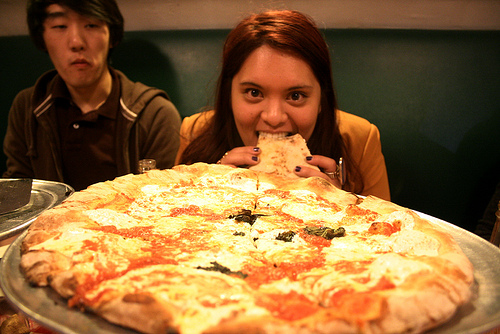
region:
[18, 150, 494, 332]
A large pizza on a silver tray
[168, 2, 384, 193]
a girl eating a piece of pizza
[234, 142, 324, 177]
the girl has blue nail polish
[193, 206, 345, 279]
basil is on the pizza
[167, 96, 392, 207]
girl is wearing a yellow shirt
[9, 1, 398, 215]
boy watching the girl eat pizza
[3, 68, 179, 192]
boy is wearing a brown hoodie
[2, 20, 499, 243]
the back of a green booth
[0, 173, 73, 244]
an empty silver tray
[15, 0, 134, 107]
a boy of Asian descent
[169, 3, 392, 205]
girl making silly face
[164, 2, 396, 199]
girl eating pizza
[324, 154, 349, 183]
large ring on girl's left hand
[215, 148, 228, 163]
rings on girl's right hand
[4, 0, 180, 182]
boy in faded hoodie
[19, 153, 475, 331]
large oven-fired pizza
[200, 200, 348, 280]
basil pesto on pizza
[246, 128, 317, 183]
pizza in girl's hands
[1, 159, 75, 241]
empty pizza tray on left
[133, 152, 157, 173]
coat of arms on boy's hoodie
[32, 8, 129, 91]
The man is impressed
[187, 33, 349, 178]
She is eating pizza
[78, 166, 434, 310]
The pizza is shiny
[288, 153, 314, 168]
her Fingernails are black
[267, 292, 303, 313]
The tomatoes are red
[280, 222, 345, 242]
The olives are black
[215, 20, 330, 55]
Her hair is red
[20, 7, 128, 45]
His hair is black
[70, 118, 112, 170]
His shirt is brown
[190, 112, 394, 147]
Her coat is orange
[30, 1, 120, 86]
man with tongue in cheek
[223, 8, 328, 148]
woman eating slice of pizza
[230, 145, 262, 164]
two fingers with dark nail polish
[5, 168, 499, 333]
pizza on a silver tray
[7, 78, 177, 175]
brown shirt and brown hoodie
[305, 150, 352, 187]
finger with large ring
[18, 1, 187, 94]
head of man with shadow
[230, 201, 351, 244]
dark garnish on top of pizza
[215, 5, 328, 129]
woman's face with reddish hair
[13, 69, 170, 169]
brown hoodie with white stripes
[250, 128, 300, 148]
THE GIRL IS BITING THE PIZZA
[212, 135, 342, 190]
THE GIRL IS HOLDING A PIZZA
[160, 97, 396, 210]
THE GIRL IS WEARING A YELLOW JACKET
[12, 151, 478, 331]
THE PIZZA IS ON A TRAY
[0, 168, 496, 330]
THE PIZZA IS VERY BIG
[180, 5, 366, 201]
THE GIRL IS EATING THE PIZZA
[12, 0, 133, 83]
THE BOY HAS BLACK HAIR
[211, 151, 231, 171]
THE GIRL IS WEARING RINGS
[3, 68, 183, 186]
THE BOY IS WEARING A HOODIE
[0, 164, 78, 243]
THE TRAY IS EMPTY